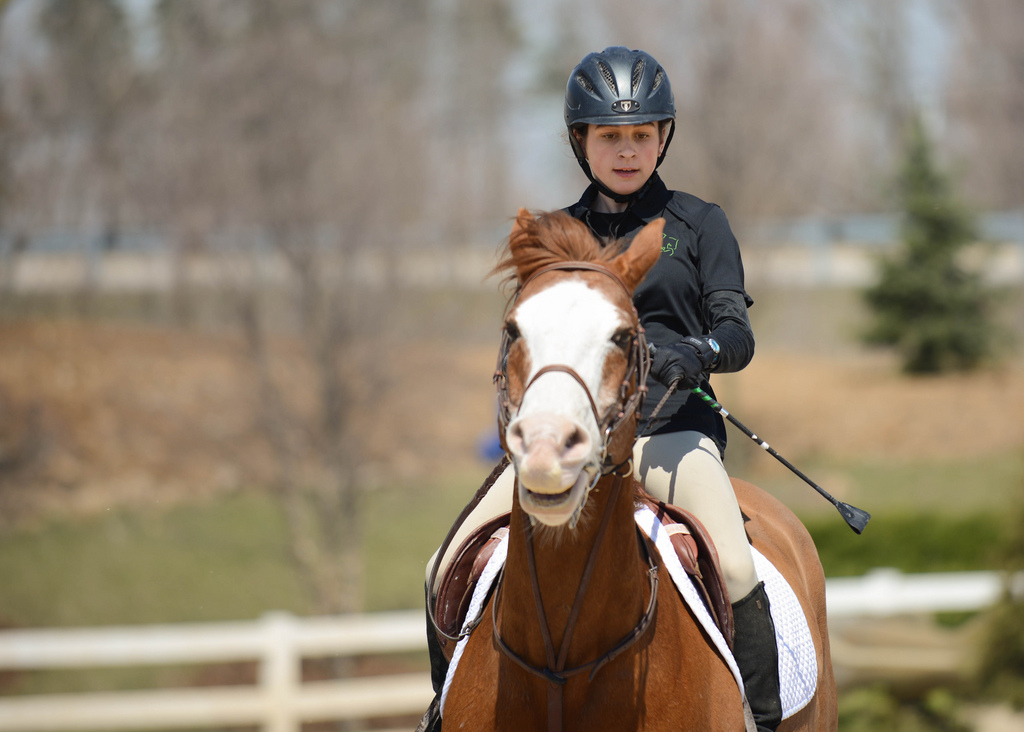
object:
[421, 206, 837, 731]
horse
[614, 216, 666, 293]
ear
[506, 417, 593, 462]
nose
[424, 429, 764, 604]
pants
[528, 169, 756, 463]
jacket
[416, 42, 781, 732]
girl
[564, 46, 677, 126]
helmet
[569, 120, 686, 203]
strap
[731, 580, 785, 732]
boots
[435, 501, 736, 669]
saddle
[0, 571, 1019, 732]
fence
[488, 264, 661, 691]
bridle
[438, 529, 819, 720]
blanket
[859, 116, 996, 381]
pine tree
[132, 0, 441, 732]
tree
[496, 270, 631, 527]
face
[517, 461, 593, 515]
mouth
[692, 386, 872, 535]
pole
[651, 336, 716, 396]
hand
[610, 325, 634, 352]
eye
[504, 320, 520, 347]
eye